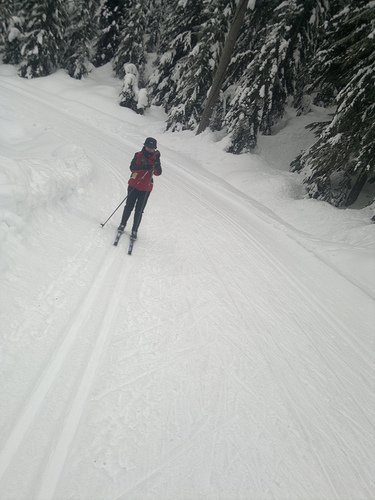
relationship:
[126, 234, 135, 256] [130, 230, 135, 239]
ski on foot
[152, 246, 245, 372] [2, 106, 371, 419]
snow on ground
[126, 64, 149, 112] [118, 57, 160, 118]
snow on tree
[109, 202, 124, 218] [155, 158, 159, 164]
ski pole in hand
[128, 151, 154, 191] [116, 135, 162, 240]
coat on lady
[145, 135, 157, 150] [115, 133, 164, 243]
hat on skier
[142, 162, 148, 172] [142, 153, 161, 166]
glove on hand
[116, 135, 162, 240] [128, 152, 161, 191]
lady has coat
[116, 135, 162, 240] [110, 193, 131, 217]
lady holding ski pole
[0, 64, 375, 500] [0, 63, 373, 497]
snow on slope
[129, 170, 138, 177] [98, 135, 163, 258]
pocket on skier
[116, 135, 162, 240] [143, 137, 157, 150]
lady wearing hat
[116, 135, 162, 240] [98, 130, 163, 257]
lady holding ski pole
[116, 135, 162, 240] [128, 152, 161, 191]
lady wearing coat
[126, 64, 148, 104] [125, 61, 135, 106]
snow covers branch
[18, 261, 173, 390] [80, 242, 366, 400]
marks on trail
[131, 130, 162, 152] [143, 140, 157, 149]
hat with visor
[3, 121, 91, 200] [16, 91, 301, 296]
side bank of a ski trail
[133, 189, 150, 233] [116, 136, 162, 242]
leg of a lady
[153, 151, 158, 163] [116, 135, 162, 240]
hand of a lady